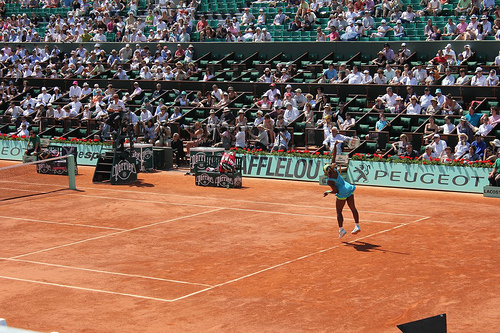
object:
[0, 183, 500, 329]
ground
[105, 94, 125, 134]
official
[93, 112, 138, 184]
green stand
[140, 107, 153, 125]
spectactors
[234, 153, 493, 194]
sign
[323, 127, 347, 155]
fan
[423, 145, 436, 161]
fan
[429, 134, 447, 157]
fan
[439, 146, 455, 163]
fan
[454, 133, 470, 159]
fan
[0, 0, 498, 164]
stands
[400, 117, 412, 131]
seat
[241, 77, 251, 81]
seat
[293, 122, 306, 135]
seat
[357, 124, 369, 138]
seat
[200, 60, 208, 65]
seat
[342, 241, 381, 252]
shadow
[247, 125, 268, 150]
person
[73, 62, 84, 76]
spectators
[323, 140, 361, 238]
athlete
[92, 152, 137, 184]
staircase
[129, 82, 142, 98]
person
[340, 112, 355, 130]
person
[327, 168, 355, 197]
shirt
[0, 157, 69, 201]
net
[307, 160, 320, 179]
letters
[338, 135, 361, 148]
racket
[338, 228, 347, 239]
shoe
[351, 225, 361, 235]
shoe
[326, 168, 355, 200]
dress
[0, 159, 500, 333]
court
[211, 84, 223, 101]
person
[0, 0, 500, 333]
match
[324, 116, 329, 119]
ball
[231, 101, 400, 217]
air